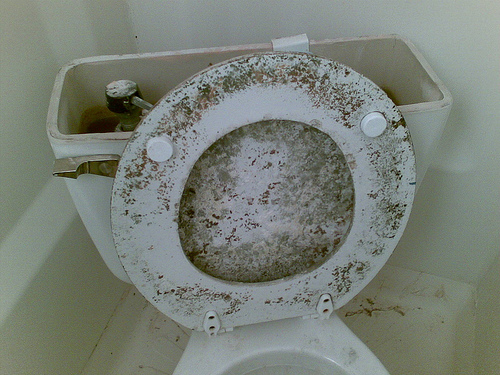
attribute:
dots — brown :
[323, 181, 399, 311]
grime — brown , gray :
[164, 98, 369, 300]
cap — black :
[70, 48, 169, 126]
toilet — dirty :
[73, 55, 448, 370]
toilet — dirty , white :
[44, 22, 440, 330]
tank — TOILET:
[61, 30, 420, 127]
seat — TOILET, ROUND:
[106, 56, 410, 339]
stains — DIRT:
[172, 91, 214, 110]